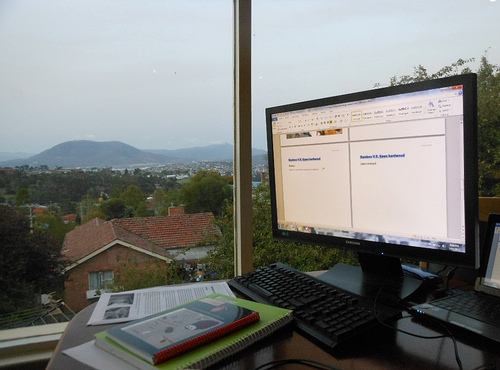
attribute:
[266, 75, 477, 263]
screen — flat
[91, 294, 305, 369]
book — green, small, spiral, binded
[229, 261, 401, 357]
keyboard — black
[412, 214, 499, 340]
laptop — open, black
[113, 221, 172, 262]
roof — red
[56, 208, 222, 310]
house — brown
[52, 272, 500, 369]
desk — brown, wooden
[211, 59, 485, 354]
computer — black, sitting, on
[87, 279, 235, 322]
paper — white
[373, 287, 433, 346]
wire — black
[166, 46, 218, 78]
clouds — white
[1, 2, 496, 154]
sky — blue, cloudy